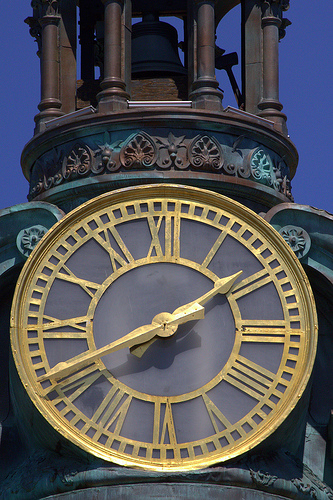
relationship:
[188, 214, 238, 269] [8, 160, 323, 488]
roman numeral on clock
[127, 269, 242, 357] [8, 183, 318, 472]
hand on clock